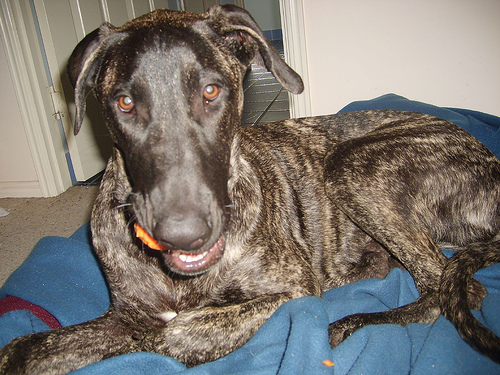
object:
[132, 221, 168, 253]
ball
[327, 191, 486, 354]
leg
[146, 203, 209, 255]
nose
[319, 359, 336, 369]
crumbs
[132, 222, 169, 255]
bread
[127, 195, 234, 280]
mouth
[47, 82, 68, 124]
hinge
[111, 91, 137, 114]
eye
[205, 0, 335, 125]
ear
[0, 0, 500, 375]
dog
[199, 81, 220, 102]
brown eye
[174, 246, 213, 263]
teeth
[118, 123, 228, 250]
snout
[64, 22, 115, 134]
ear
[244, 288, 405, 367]
blanket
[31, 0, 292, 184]
door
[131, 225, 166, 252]
object